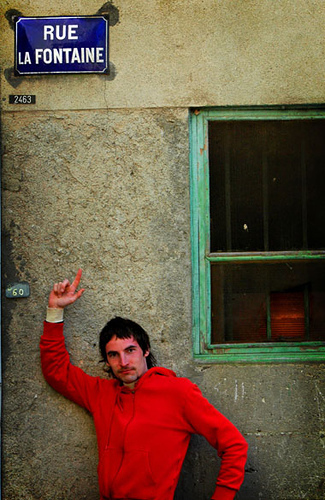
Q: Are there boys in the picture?
A: No, there are no boys.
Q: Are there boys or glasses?
A: No, there are no boys or glasses.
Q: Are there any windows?
A: Yes, there is a window.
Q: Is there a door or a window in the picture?
A: Yes, there is a window.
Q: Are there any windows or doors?
A: Yes, there is a window.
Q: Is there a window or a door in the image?
A: Yes, there is a window.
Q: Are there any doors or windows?
A: Yes, there is a window.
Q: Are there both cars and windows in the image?
A: No, there is a window but no cars.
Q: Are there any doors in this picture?
A: No, there are no doors.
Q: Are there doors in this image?
A: No, there are no doors.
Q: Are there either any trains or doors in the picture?
A: No, there are no doors or trains.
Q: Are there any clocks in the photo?
A: No, there are no clocks.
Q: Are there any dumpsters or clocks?
A: No, there are no clocks or dumpsters.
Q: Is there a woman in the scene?
A: No, there are no women.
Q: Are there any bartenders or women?
A: No, there are no women or bartenders.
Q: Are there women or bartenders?
A: No, there are no women or bartenders.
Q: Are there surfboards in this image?
A: No, there are no surfboards.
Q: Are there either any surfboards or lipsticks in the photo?
A: No, there are no surfboards or lipsticks.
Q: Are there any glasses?
A: No, there are no glasses.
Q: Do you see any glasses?
A: No, there are no glasses.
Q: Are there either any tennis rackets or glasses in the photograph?
A: No, there are no glasses or tennis rackets.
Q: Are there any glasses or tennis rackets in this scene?
A: No, there are no glasses or tennis rackets.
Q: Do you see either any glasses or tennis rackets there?
A: No, there are no glasses or tennis rackets.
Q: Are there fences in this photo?
A: No, there are no fences.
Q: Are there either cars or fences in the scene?
A: No, there are no fences or cars.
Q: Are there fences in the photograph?
A: No, there are no fences.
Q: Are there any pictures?
A: No, there are no pictures.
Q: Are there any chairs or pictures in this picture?
A: No, there are no pictures or chairs.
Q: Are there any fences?
A: No, there are no fences.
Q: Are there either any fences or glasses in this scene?
A: No, there are no fences or glasses.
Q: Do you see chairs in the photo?
A: No, there are no chairs.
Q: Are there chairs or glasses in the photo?
A: No, there are no chairs or glasses.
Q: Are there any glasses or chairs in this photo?
A: No, there are no chairs or glasses.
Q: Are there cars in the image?
A: No, there are no cars.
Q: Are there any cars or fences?
A: No, there are no cars or fences.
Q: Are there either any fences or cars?
A: No, there are no cars or fences.